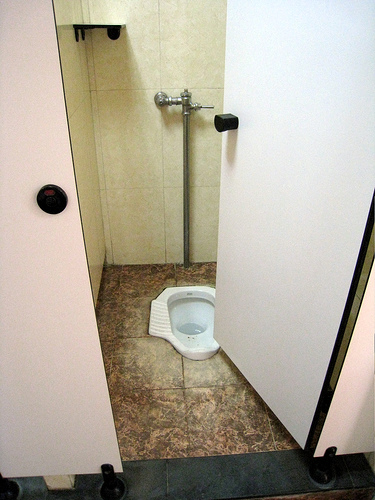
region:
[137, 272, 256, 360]
Toilet in the floor of tile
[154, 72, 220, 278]
Very tall flush handle for a toilet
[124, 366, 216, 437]
Beautiful marbled floor tile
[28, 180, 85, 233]
Door handle lock and opener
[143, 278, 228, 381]
Interesting toilet placed within the floor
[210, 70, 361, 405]
very low ending bathroom public door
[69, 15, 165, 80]
A cell phone and accessories shelf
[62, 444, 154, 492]
Strong wall holders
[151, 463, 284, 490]
Dark green floor tiles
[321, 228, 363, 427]
the crack between a public bathroom door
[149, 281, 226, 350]
this is a toilet sink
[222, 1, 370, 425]
the door is opened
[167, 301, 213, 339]
the toilet sink is white in color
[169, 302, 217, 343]
the toilet sink is clean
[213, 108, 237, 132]
this is the doors handle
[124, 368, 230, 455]
the floor is made of tiles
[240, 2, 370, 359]
the door is white in color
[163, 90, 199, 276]
this is a metallic pipe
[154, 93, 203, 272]
the metallic pipe is shiny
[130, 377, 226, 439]
the floor is brown in color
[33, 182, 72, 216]
Round black thing on a white wall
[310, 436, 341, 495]
Right foot of a partitioned wall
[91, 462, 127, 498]
Middle foot of a partitioned wall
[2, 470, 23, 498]
left foot of a partitioned wall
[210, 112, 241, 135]
Bathroom door handle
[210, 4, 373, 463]
white door leading to the bathroom stall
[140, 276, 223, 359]
White basin for using the bathroom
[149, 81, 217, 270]
stainless steel bathroom fixtures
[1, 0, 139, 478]
left side white partitioned wall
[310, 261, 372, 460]
Right side white partitioned wall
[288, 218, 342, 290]
part of a white door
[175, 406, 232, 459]
part of a toilet floor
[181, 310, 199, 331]
hole of a toilet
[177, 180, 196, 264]
a metal pole holding the tamk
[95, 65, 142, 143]
part of the toilet wall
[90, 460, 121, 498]
part of a black holder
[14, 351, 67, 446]
part of a white wall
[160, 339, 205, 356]
white edge of a toilet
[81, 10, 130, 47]
part of a black shelf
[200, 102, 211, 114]
part of a bolt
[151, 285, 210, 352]
this is a toilet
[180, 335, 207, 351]
the toilet is white in color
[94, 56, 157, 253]
this is the toilet wall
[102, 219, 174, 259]
the wall is made of tiles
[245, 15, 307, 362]
this is the door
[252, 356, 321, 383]
the door is made of wood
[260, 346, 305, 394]
the door is white in color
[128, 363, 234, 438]
this is the floor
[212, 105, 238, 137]
this is the door lock